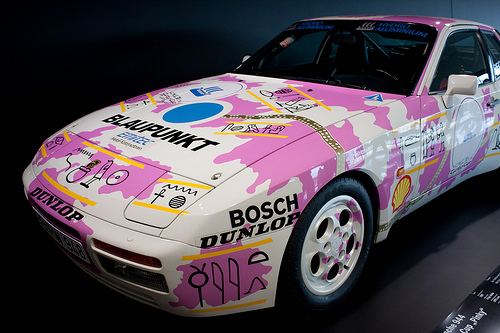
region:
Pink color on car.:
[215, 132, 307, 202]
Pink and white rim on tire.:
[297, 172, 384, 293]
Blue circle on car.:
[158, 94, 228, 141]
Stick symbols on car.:
[68, 143, 112, 195]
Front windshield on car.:
[263, 17, 442, 102]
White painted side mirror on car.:
[428, 61, 497, 136]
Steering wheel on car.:
[340, 57, 406, 102]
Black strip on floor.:
[435, 265, 483, 330]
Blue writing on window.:
[362, 13, 423, 49]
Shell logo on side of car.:
[383, 170, 430, 222]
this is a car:
[18, 16, 478, 298]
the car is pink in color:
[273, 129, 309, 171]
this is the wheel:
[299, 182, 375, 293]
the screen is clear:
[323, 22, 402, 83]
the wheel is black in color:
[344, 173, 359, 192]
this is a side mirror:
[442, 70, 476, 102]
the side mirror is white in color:
[446, 72, 480, 95]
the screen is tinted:
[298, 38, 385, 76]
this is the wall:
[169, 12, 205, 52]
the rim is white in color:
[321, 214, 360, 268]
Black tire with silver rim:
[286, 171, 386, 311]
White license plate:
[29, 203, 96, 271]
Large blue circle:
[155, 91, 236, 132]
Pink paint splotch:
[212, 112, 374, 210]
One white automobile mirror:
[443, 68, 479, 98]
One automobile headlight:
[83, 248, 173, 296]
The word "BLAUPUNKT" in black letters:
[100, 107, 221, 153]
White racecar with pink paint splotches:
[18, 11, 498, 318]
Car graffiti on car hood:
[48, 145, 214, 220]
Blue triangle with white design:
[361, 88, 385, 107]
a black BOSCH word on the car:
[227, 195, 300, 225]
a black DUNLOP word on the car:
[30, 184, 91, 221]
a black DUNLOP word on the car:
[202, 213, 307, 250]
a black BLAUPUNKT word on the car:
[105, 108, 227, 158]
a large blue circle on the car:
[164, 96, 228, 132]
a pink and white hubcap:
[302, 197, 366, 290]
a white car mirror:
[445, 68, 480, 98]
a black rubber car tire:
[297, 173, 374, 305]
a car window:
[435, 28, 492, 94]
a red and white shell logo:
[387, 167, 412, 207]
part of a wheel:
[306, 220, 360, 302]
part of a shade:
[371, 246, 423, 296]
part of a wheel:
[286, 186, 351, 278]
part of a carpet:
[393, 241, 436, 308]